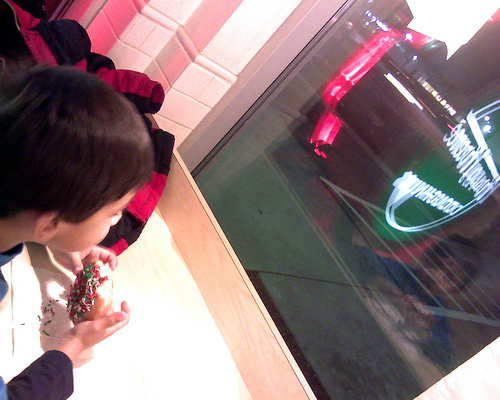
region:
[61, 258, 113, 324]
Doughnut in child's hands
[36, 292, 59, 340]
Sprinkles falling onto table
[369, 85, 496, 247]
Green store logo reflected in window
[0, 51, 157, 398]
Child looking out the window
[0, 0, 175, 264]
Red and black jacket resting on table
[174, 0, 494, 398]
Window at doughnut shop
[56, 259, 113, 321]
a sprinkle-covered doughnut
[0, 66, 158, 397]
Child holding a doughnut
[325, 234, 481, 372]
Reflection of child in window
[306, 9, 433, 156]
Red light reflection in window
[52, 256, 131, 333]
donut with sprinkles on it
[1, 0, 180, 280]
pink and black jacket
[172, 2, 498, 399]
neon pink reflection in a plate glass window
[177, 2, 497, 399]
reflection of a little boy in a plate glass window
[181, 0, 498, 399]
green and white sign blurrily reflected in a plate glass window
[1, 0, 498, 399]
boy sitting in front of a window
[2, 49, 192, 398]
boy with brown hair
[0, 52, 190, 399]
boy eating a donut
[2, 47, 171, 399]
boy eating a donut with sprinkles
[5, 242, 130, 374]
green, red, and white sprinkles falling off of a donut onto a napkin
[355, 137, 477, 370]
reflection of boy in window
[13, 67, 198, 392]
boy eating donut with sprinkles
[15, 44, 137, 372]
boy holding a donut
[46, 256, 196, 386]
donut with red, white, and green sprinkles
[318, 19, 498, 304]
reflection of items in store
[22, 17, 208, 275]
a boy's heavy coat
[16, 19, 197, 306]
black and red checkered coat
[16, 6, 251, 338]
red and black checkered coat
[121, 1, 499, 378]
window in a restaurant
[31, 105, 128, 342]
A little boy eating a donut.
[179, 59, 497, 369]
A person looking out the window.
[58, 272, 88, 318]
The donut has sprinkles.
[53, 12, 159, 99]
A jacket on the counter.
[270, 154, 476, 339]
The boy reflection in the window.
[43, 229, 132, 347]
The boy is holding a donut.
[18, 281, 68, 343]
Sprinkles on the counter.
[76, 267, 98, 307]
The sprinkles are green red and white.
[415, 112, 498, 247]
A green sign lighted up.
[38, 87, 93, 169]
The boy has black hair.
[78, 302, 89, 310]
colored sprinkle on donut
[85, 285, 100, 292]
colored sprinkle on donut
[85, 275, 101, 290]
colored sprinkle on donut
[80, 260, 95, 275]
colored sprinkle on donut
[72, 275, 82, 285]
colored sprinkle on donut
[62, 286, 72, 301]
colored sprinkle on donut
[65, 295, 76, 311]
colored sprinkle on donut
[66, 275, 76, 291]
colored sprinkle on donut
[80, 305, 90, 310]
colored sprinkle on donut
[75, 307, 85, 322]
colored sprinkle on donut